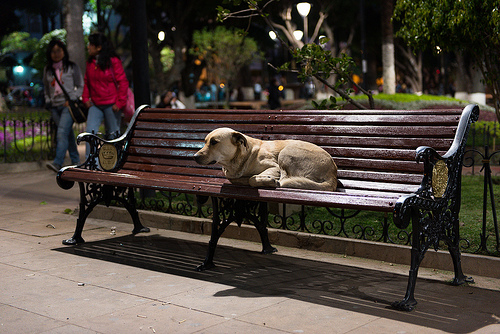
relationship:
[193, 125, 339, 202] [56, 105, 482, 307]
dog sitting on bench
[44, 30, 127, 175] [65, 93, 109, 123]
girls holding bags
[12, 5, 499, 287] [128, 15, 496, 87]
park has trees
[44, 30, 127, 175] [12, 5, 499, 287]
females in park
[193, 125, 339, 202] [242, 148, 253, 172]
dog has collar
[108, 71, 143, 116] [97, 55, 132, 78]
bag over shoulder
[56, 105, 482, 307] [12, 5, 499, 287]
bench in park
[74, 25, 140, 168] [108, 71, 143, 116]
girl carrying bag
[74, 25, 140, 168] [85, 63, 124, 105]
girl wearing jacket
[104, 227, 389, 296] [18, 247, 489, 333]
shadow on sidewalk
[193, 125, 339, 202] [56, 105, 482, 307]
dog lying on bench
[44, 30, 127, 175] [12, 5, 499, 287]
girls walking in park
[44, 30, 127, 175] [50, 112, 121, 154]
girls wearing jeans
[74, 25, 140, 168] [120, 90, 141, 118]
girl wearing purse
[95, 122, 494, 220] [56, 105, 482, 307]
fence behind bench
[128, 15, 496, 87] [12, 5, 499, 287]
trees in park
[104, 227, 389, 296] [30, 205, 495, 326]
shadow on ground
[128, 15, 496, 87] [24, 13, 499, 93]
trees in background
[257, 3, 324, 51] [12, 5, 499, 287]
lights in park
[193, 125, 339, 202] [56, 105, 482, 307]
dog on top of bench